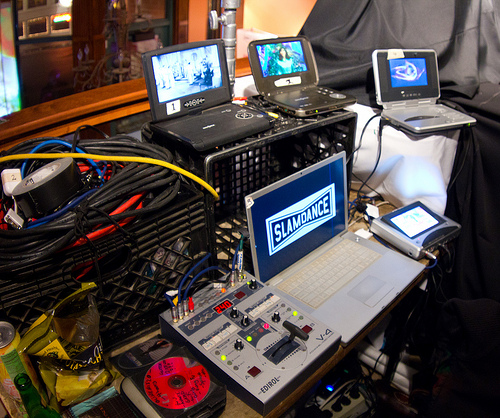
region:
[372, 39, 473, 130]
A small computer laptop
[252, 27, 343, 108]
A small computer laptop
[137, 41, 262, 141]
A small computer laptop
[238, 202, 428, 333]
A big computer laptop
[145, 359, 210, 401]
An orange compact disk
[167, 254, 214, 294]
A green computer cable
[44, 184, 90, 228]
A green computer cable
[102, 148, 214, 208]
A yellow computer cable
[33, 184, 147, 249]
A black computer cable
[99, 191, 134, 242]
An orange computer cable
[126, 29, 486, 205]
three DVD players on cases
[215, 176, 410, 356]
grey laptop near electronics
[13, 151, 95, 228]
black roll of tape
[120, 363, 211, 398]
red disc near laptop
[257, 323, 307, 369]
black throw switch near laptop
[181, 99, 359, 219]
black crate under DVD players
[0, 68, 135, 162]
brown ledge behind DVD players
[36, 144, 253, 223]
yellow ethernet cable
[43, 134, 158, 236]
large roll of black cable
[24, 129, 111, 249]
blue cable under black tape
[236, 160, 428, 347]
the laptop is grey in color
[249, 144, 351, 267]
the laptop is turned on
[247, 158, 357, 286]
the display monitor is on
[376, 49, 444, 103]
the display is turned on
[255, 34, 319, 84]
the display is turned on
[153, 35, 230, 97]
the display is turned on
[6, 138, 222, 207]
a cable is in the crate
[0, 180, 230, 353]
the crate is black in color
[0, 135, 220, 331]
the crate is made of plastic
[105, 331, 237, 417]
a stack of music cds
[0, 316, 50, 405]
a drink can on a table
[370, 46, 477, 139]
a portable dvd player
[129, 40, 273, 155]
a portable dvd player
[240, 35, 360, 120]
a portable dvd player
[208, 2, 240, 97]
a metal pipe with a handle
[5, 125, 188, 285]
a stack of black cables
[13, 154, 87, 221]
a roll of duct tape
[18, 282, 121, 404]
a bag of potato chips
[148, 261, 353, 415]
a machine with the words EDIROL on it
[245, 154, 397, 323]
grey laptop is on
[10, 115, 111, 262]
blue cable under roll of tape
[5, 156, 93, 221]
black roll of tape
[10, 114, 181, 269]
large black rolled up cable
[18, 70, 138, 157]
brown ledge behind DVD players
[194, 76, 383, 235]
black crate under DVD players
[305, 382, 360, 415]
surge protector under table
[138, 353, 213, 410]
A red CD with black writing on the front of it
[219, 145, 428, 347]
compute on a desk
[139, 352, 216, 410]
a red disk on the desk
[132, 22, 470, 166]
a group of dvd players